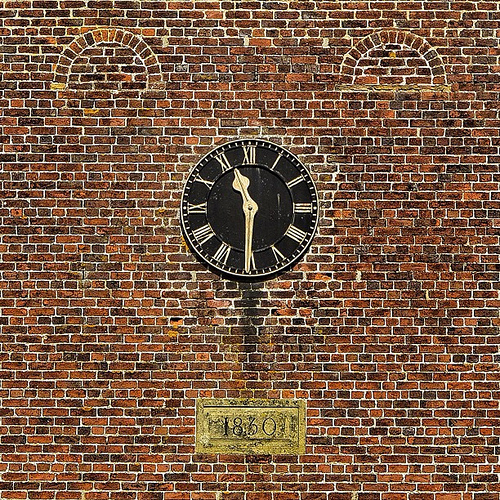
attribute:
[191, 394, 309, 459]
year plate — year 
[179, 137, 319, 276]
black clock — big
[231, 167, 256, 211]
gold hand — two thick gold clock 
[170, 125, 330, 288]
clock — black , gold 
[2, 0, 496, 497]
building —  bricks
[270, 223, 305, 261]
roman — numerials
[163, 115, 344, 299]
clock — circle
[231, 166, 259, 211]
hand — clock, brass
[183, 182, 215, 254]
roman numerals — roman 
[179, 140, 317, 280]
clock — big, black, hand , 11:30, circle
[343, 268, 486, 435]
brown —  black 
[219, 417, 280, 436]
black numbers — black 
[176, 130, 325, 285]
clock — black , gold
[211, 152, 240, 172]
numerals — Roman 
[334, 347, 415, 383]
bricks —  brown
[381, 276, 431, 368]
building — bricks 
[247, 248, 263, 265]
numeral — roman 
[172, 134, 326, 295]
clock — numbers , white, big, black, wall/